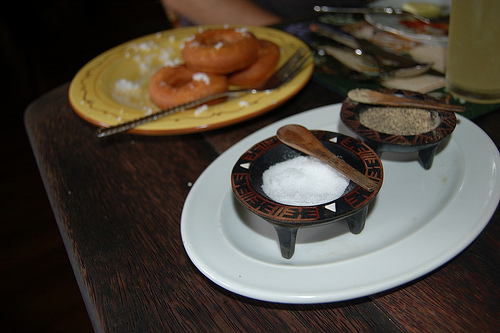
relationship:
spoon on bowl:
[300, 85, 467, 113] [339, 88, 459, 169]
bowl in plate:
[339, 89, 459, 168] [177, 94, 499, 300]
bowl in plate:
[239, 126, 387, 261] [69, 27, 307, 138]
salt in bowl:
[256, 151, 352, 210] [239, 126, 387, 261]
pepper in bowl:
[358, 105, 442, 135] [239, 126, 387, 261]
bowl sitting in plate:
[239, 126, 386, 259] [145, 129, 497, 307]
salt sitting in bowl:
[256, 151, 352, 210] [225, 97, 456, 242]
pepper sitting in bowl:
[358, 105, 442, 135] [225, 97, 456, 242]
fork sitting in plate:
[90, 44, 316, 145] [64, 9, 321, 132]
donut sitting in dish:
[184, 28, 256, 77] [179, 95, 500, 306]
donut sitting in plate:
[184, 28, 256, 77] [64, 20, 321, 148]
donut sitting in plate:
[225, 38, 284, 86] [64, 20, 321, 148]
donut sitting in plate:
[149, 64, 224, 112] [64, 20, 321, 148]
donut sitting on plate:
[184, 28, 256, 77] [64, 37, 337, 134]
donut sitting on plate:
[184, 28, 256, 71] [177, 94, 499, 300]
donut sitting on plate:
[153, 67, 226, 102] [69, 27, 307, 138]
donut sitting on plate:
[237, 43, 284, 80] [177, 94, 499, 300]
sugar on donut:
[186, 68, 212, 88] [193, 25, 270, 71]